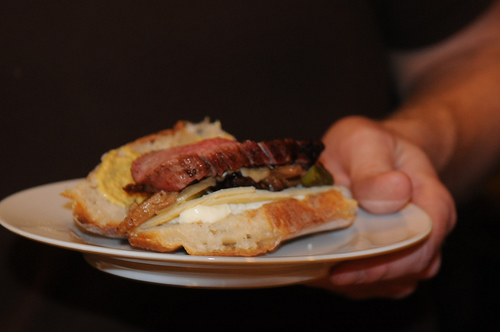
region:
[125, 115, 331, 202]
meat on sandwich roll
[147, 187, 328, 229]
cheese slices on sandwich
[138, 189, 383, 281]
mayonnaise on sandwich roll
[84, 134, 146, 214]
mustard on sandwich roll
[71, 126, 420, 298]
sandwich on white plate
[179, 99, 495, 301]
hand holding white plate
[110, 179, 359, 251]
white inside of bread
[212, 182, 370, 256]
golden brown outside of bread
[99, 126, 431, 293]
open sandwich on plate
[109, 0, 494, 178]
person wearing black shirt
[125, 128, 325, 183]
The meat is sliced.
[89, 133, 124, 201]
The mustard is on the sandwhich.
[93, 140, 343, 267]
The bread is white.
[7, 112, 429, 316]
The plate is white.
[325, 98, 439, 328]
He is holding the plate.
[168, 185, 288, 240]
mayo is on the sandwhich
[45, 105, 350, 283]
The sandwhich is on the plate.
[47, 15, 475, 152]
The man is wearing a black jacket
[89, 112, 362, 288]
The sandwhich is toasted.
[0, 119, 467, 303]
The plate is small.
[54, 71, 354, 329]
a plate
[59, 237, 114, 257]
Rim of white plate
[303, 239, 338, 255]
Face of white plate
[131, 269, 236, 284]
Bottom of white plate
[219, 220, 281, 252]
Top side of bread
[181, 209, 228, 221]
Mayonaise on the bread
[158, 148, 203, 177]
Meat on top of bread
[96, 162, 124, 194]
Egg on the bread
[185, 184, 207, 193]
Onions under meat on bread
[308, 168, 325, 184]
Green pickles on bread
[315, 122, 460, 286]
Hand holding a plate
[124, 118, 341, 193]
grilled greasy hot dog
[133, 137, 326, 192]
hot dog cut in 2 pieces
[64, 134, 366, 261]
hot dog on a bread bun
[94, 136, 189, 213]
yellow mustard on a hot dog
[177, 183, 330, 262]
mayonnaise on crusty bread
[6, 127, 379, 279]
hot dog on a white plate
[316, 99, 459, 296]
hand holding white plate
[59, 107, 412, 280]
junk food on a plate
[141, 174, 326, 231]
slice of cheese on top of a bread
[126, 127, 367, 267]
meat with bread as a meal